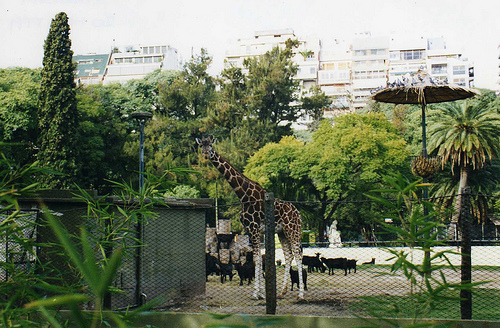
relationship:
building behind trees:
[67, 35, 498, 127] [20, 17, 497, 243]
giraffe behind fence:
[193, 135, 315, 305] [25, 199, 493, 321]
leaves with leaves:
[363, 172, 490, 316] [359, 175, 476, 315]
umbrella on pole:
[371, 67, 476, 106] [417, 102, 429, 269]